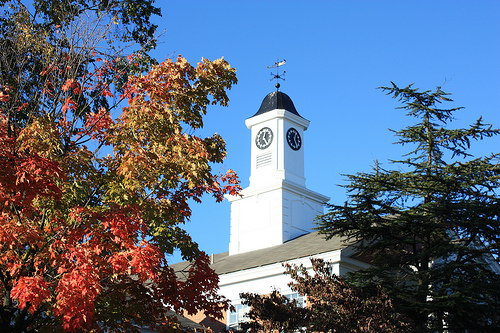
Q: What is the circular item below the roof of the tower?
A: Clock.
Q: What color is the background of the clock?
A: Black.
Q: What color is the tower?
A: White.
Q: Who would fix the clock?
A: Clocksmith.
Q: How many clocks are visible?
A: Two.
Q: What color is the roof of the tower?
A: Black.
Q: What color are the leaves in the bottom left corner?
A: Orange.